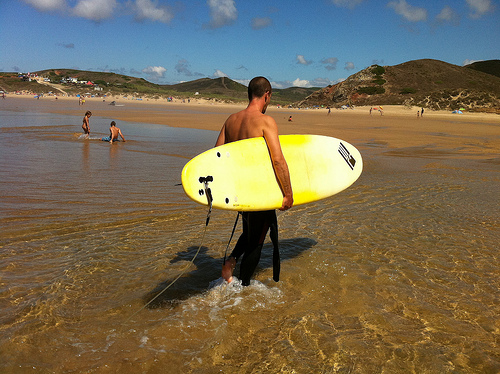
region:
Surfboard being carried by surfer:
[168, 124, 380, 222]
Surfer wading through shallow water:
[178, 78, 302, 325]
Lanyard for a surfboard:
[87, 164, 225, 346]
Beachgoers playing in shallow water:
[77, 103, 124, 160]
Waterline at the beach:
[377, 135, 496, 181]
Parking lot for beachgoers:
[20, 73, 105, 99]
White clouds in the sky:
[193, 0, 239, 41]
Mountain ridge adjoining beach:
[322, 51, 491, 118]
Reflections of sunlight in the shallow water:
[350, 253, 437, 343]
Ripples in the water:
[27, 180, 122, 248]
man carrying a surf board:
[169, 40, 375, 307]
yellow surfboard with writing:
[180, 95, 386, 225]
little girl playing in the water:
[77, 99, 97, 139]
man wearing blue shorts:
[93, 113, 125, 154]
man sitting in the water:
[94, 115, 137, 157]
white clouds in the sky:
[42, 2, 469, 67]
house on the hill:
[60, 72, 100, 90]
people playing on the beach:
[366, 97, 386, 118]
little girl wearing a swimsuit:
[70, 97, 106, 147]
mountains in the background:
[310, 51, 475, 121]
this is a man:
[213, 79, 315, 250]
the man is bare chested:
[227, 105, 264, 134]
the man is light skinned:
[252, 112, 270, 119]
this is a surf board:
[298, 134, 333, 189]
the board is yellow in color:
[291, 143, 328, 185]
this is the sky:
[265, 7, 399, 54]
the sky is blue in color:
[302, 15, 372, 50]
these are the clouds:
[73, 7, 155, 21]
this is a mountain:
[358, 60, 463, 87]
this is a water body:
[6, 140, 98, 192]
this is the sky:
[201, 38, 267, 63]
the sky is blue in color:
[159, 36, 216, 53]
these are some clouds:
[84, 4, 246, 25]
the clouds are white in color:
[84, 1, 111, 21]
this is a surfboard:
[183, 140, 364, 202]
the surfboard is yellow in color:
[285, 135, 296, 147]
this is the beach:
[133, 103, 178, 153]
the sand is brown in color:
[393, 110, 407, 127]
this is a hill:
[373, 61, 483, 99]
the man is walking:
[218, 82, 290, 297]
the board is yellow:
[206, 144, 351, 214]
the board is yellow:
[195, 133, 391, 303]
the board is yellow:
[217, 146, 319, 256]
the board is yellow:
[175, 65, 335, 215]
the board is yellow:
[175, 120, 290, 222]